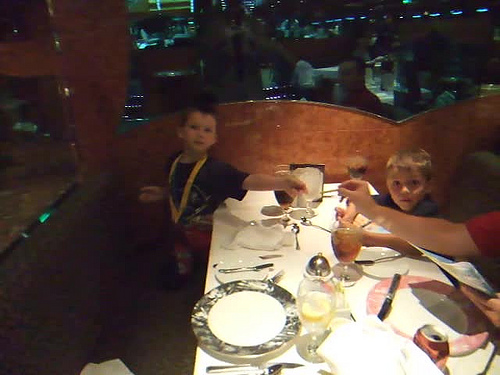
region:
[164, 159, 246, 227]
black cotton tee shirt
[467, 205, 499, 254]
red sleeve of shirt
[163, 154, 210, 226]
yellow lanyard on neck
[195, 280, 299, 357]
green and white plate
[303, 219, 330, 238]
silver metal spoon on table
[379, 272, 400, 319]
silver metal butter knife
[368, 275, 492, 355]
pink and white plate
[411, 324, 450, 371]
soda can on table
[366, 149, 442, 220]
boy sitting at table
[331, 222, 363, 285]
drinking glass on table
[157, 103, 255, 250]
boy sitting at the table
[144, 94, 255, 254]
boy wearing black shirt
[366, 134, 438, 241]
boy looking at the camera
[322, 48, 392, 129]
man wearing red shirt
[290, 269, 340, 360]
wine glass filled with wine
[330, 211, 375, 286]
wine glass with ice tea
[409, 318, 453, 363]
can of soda on the table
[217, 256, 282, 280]
butter knife on the plate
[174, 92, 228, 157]
head of a person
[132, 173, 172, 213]
arm of a person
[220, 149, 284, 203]
arm of a person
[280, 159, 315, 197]
hand of a person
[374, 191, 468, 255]
arm of a person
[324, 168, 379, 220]
hand of a person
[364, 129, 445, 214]
head of a person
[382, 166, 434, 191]
eye of a person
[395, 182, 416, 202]
nose of a person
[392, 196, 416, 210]
mouth of a person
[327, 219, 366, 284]
wine glass on the table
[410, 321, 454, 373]
soda can on the table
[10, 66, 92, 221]
mirror on the wall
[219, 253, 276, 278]
knife on the plate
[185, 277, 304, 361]
plate on the table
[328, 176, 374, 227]
hands on the table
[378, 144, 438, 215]
boy with blonde hair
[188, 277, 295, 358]
White plate with decorated border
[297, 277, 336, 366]
Clear glass with wine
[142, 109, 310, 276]
Small boy in black shirt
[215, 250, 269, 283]
Small white plate on table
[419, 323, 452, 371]
Metal soda can on table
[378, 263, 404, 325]
Silver table knife on plate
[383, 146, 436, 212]
Head of small boy at table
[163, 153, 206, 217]
Yellow strap around boy's neck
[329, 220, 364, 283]
Short glass with liquid inside